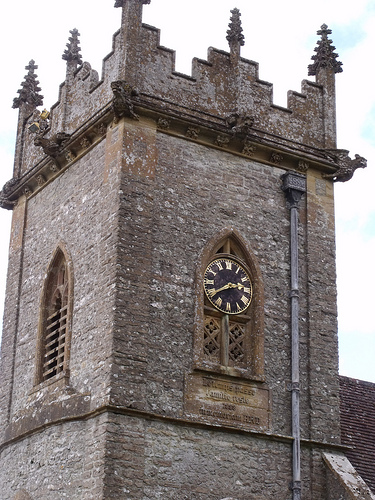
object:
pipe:
[288, 196, 302, 498]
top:
[1, 0, 368, 215]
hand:
[208, 285, 228, 296]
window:
[35, 240, 70, 383]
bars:
[42, 305, 62, 376]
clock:
[202, 256, 254, 314]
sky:
[326, 11, 367, 51]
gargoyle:
[32, 134, 69, 157]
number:
[222, 261, 232, 271]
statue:
[226, 10, 245, 59]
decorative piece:
[109, 78, 139, 124]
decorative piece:
[226, 111, 256, 142]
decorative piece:
[321, 148, 367, 183]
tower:
[1, 4, 373, 495]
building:
[3, 0, 375, 498]